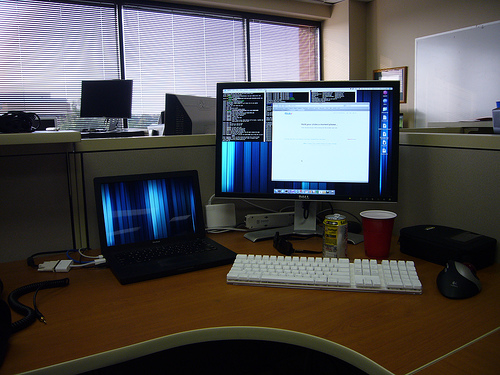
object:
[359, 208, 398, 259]
cup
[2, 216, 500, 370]
desk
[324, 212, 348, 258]
can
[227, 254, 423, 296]
keyboard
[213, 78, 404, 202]
monitor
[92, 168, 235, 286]
laptop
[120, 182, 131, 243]
lines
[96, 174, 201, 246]
screen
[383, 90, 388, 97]
icons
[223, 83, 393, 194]
screen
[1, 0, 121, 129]
blinds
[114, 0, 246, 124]
window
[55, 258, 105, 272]
cables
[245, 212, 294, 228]
strip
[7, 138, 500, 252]
wall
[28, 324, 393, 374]
edge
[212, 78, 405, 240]
desktop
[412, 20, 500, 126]
board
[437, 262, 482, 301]
mouse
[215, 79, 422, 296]
computers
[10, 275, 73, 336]
cords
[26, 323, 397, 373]
curve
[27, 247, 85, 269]
wires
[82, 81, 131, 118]
screen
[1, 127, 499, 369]
cubicle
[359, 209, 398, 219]
trim